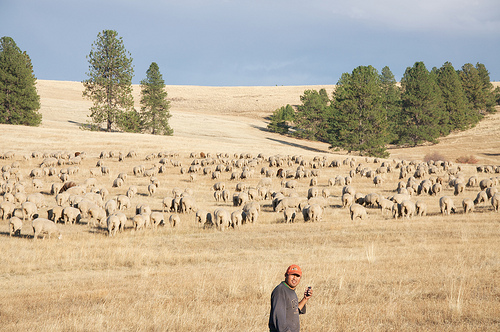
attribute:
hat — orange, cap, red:
[285, 264, 306, 276]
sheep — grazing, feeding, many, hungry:
[161, 150, 411, 228]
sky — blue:
[174, 13, 424, 53]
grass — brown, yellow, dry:
[201, 94, 257, 123]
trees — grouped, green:
[83, 40, 175, 118]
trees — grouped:
[309, 71, 488, 121]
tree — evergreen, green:
[136, 67, 179, 114]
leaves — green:
[344, 72, 353, 82]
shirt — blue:
[267, 286, 303, 327]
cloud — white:
[413, 8, 452, 34]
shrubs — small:
[273, 101, 290, 128]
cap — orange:
[289, 263, 310, 273]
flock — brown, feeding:
[255, 149, 371, 199]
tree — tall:
[100, 30, 137, 139]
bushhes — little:
[277, 105, 295, 133]